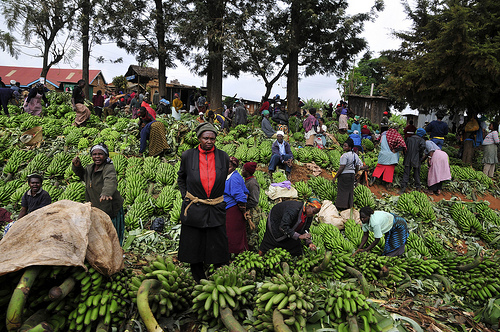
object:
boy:
[16, 171, 52, 209]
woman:
[353, 204, 408, 258]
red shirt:
[197, 148, 214, 193]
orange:
[196, 147, 214, 194]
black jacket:
[175, 146, 231, 208]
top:
[186, 140, 224, 201]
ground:
[0, 104, 497, 330]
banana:
[350, 296, 357, 313]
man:
[265, 130, 297, 176]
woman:
[164, 119, 253, 266]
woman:
[72, 143, 122, 244]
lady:
[259, 194, 317, 253]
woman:
[330, 131, 369, 208]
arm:
[99, 166, 119, 193]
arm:
[74, 165, 86, 181]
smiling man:
[20, 172, 51, 206]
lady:
[74, 147, 119, 207]